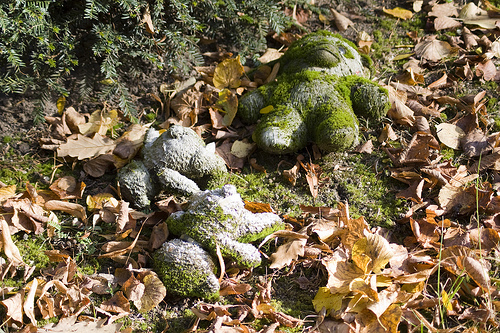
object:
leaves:
[45, 129, 121, 164]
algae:
[240, 170, 272, 184]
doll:
[150, 180, 282, 301]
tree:
[0, 1, 292, 119]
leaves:
[321, 263, 369, 298]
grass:
[419, 258, 479, 306]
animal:
[237, 34, 388, 158]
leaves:
[410, 210, 448, 248]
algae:
[260, 78, 292, 117]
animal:
[115, 114, 220, 206]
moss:
[260, 91, 304, 128]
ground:
[0, 0, 499, 333]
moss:
[283, 71, 346, 101]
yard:
[0, 1, 500, 331]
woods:
[0, 0, 500, 333]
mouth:
[307, 41, 340, 66]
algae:
[167, 260, 204, 283]